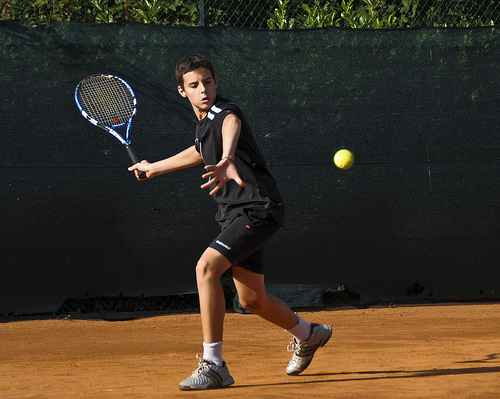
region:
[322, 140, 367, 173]
yellow tennis ball in mid air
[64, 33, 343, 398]
male tennis player about to hit ball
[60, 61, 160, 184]
tennis racket in man's hand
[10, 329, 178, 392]
dirt ground of a tennis court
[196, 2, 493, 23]
green chain link fence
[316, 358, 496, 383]
shadow casted on the ground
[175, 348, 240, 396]
left sneaker of the tennis player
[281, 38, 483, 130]
green screen attached to fence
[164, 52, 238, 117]
face of a male tennis player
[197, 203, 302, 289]
black shorts on the tennis player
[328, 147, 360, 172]
yellow tennis ball about to be hit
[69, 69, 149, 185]
blue, black and white tennis racket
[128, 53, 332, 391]
man in black outfit playing tennis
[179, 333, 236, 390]
gray tennis shoe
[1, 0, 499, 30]
green foliage visible behind chain link fence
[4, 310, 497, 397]
brown tennis court ground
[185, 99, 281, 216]
black tank top with white stripes on shoulder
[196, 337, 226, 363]
white socks pulled up above ankle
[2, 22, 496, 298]
black cover on chain link fence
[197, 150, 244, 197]
left hand is open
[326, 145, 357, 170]
green tennis ball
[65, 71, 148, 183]
black handle blue tennis racket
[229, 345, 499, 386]
black shadow of tennis player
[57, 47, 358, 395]
boy preparing to hit tennis ball with tennis racket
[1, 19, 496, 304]
green tarp over metal fence on tennis court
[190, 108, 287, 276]
black short sleeve shirt and black shorts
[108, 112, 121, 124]
red dot at bottom of tennis racket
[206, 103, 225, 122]
two white stripes on shoulder of black shirt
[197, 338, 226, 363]
short white cotton socks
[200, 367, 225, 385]
three stripe Adidas logo side of sneaker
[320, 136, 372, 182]
this is a green ball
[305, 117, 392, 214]
a flying tennis ball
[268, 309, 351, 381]
this is the right shoe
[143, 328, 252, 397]
this is the left shoe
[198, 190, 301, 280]
these are black shorts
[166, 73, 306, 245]
this is a black shirt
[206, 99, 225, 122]
bright white shoulder stripes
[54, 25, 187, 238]
a blue tennis racket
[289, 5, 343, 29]
these are green leaves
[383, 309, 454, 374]
this is brown dirt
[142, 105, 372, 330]
the man's outfit is black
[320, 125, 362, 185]
the tennis ball is yellow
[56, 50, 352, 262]
the man is hitting the ball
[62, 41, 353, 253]
the man is holding a tennis racket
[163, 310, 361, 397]
the man's shoes are gray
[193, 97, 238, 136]
the man's shirt has white stripes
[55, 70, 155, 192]
the tennis racket is blue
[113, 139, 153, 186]
the handle is black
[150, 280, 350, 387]
the man's socks are white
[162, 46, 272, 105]
the man's hair is black